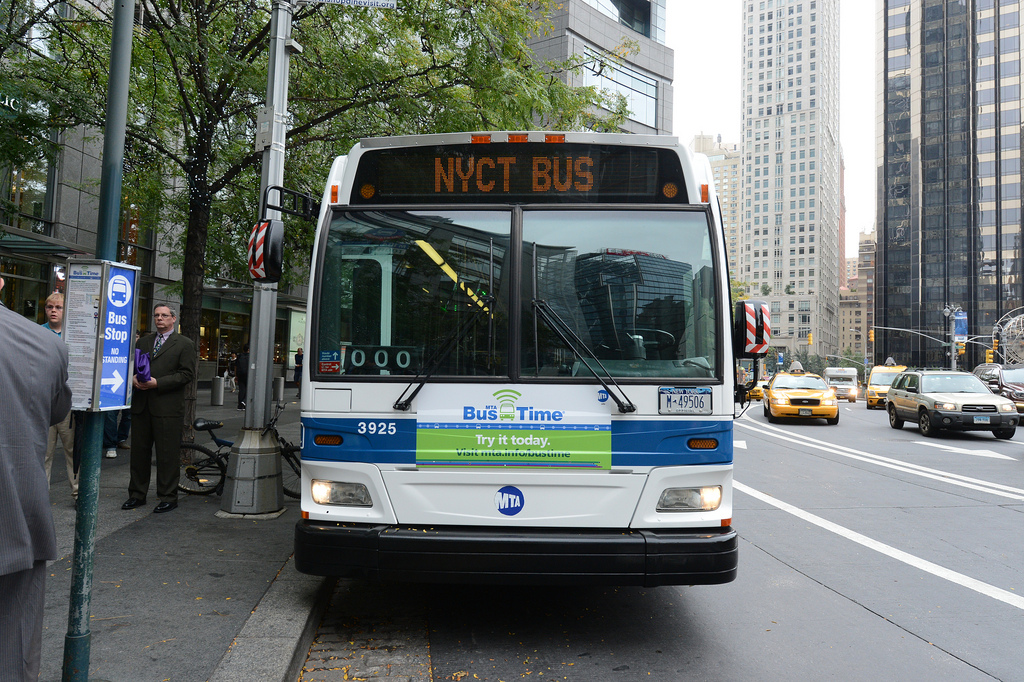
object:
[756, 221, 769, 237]
window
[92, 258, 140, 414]
sign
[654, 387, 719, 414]
plate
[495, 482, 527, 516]
logo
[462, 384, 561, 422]
logo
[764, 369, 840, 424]
taxi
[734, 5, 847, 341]
building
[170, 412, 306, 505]
bike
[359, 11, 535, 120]
leaves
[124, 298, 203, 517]
man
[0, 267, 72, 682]
man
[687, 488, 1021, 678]
road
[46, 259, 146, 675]
bus stop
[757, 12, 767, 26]
windows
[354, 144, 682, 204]
sign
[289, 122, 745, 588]
bus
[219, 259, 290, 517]
pole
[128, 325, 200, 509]
suit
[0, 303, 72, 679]
suit